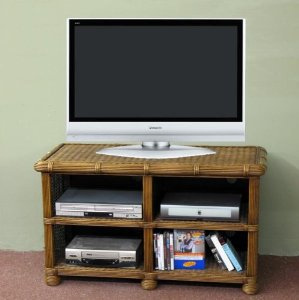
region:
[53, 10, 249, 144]
This is a TV set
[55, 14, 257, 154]
This is a white TV set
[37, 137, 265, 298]
This is a table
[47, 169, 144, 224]
Drawer of a table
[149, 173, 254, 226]
Drawer of a table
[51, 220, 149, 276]
Drawer of a table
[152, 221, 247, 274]
Drawer of a table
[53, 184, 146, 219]
a dvd player set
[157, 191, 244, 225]
a cable box set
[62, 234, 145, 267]
a vcr video set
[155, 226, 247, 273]
dvds and video cassettes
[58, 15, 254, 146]
a flat screen tv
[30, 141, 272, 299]
a small television stand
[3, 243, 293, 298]
a red carpet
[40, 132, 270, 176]
the table top of a television stand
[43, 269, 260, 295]
the underneath of the television stand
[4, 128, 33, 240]
the solid color wall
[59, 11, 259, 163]
a silver flat screen tv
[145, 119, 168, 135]
a company logo on the tv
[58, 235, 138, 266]
a black and silver Vcr player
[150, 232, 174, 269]
a collection of dvd tapes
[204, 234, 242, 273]
three vhs tapes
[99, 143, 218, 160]
an oblong base on the tv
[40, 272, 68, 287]
a brown round stand support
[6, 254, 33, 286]
red carpet on the floor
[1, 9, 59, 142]
a light green wall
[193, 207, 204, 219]
a black logo on the game box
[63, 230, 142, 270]
An VCR on the shelf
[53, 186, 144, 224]
A VCR on the shelf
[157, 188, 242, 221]
A DVD player on the shelf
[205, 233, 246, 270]
A collection of books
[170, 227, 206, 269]
A boxed set of DVDs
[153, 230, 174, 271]
A collection of DVDs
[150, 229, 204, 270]
A collection of movies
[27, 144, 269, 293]
A brown entertainment center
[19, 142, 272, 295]
A brown storage unit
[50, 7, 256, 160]
A television that is off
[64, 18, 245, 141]
a flat screen TV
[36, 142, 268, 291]
an entertainment unit against a wall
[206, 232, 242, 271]
books on a shelf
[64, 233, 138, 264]
a VHS player in an entertainment unit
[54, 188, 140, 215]
a DVD player in an entertainment unit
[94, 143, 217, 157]
white stand of a flat screen TV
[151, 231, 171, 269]
a row of books neatly stacked together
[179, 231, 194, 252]
a man crossing his arms on the cover of a book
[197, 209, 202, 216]
an apple logo on a silver console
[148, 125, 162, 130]
a logo on a TV